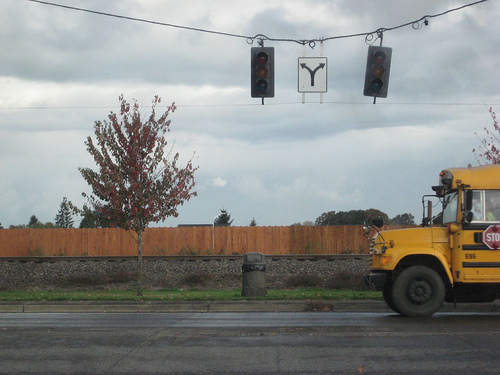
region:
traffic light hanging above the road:
[228, 21, 291, 118]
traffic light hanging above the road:
[366, 15, 400, 110]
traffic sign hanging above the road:
[289, 35, 331, 117]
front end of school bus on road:
[360, 144, 496, 343]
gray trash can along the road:
[239, 249, 279, 308]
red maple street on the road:
[85, 99, 190, 321]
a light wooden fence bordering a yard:
[0, 224, 367, 256]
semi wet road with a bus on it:
[89, 318, 375, 364]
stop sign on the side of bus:
[481, 214, 498, 252]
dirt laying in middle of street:
[237, 324, 324, 341]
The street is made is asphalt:
[48, 325, 438, 373]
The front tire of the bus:
[385, 260, 448, 322]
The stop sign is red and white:
[477, 219, 499, 256]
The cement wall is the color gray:
[38, 254, 125, 289]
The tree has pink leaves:
[80, 94, 197, 302]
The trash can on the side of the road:
[235, 245, 273, 302]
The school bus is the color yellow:
[359, 161, 497, 320]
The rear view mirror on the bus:
[455, 180, 480, 226]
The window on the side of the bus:
[468, 187, 498, 226]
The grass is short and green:
[9, 286, 175, 309]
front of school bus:
[360, 154, 498, 325]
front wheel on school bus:
[382, 257, 451, 322]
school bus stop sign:
[476, 222, 498, 248]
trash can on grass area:
[240, 250, 270, 300]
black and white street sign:
[293, 39, 332, 109]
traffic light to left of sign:
[240, 37, 282, 109]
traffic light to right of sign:
[354, 35, 397, 105]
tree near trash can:
[77, 90, 202, 297]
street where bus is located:
[5, 317, 495, 372]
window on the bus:
[482, 188, 497, 219]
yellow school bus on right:
[325, 167, 492, 291]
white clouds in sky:
[11, 8, 499, 260]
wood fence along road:
[14, 222, 437, 259]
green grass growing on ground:
[6, 278, 415, 320]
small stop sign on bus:
[480, 223, 498, 245]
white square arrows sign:
[304, 54, 332, 97]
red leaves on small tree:
[53, 100, 187, 230]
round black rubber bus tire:
[376, 273, 433, 317]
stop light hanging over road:
[233, 28, 279, 123]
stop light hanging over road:
[353, 37, 406, 134]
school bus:
[349, 147, 497, 308]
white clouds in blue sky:
[6, 21, 65, 78]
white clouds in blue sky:
[29, 68, 82, 139]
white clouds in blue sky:
[2, 113, 71, 180]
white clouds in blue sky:
[200, 125, 259, 157]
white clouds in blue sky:
[241, 157, 287, 197]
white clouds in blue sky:
[294, 111, 340, 168]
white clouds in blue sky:
[323, 108, 371, 161]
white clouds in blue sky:
[141, 37, 177, 61]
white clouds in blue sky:
[411, 35, 464, 108]